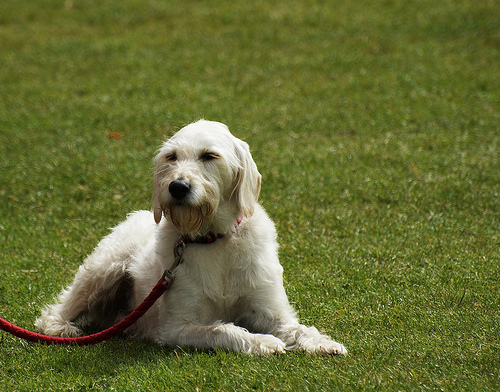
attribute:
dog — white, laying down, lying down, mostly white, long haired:
[29, 117, 352, 360]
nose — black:
[168, 174, 192, 200]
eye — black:
[197, 149, 220, 163]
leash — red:
[0, 205, 251, 348]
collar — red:
[165, 207, 244, 246]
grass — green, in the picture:
[0, 0, 499, 392]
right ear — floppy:
[148, 145, 167, 223]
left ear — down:
[233, 139, 263, 220]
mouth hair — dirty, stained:
[155, 198, 217, 229]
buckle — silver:
[163, 234, 186, 283]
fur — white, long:
[30, 117, 350, 358]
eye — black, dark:
[159, 146, 179, 163]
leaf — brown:
[105, 131, 123, 143]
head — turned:
[146, 117, 264, 238]